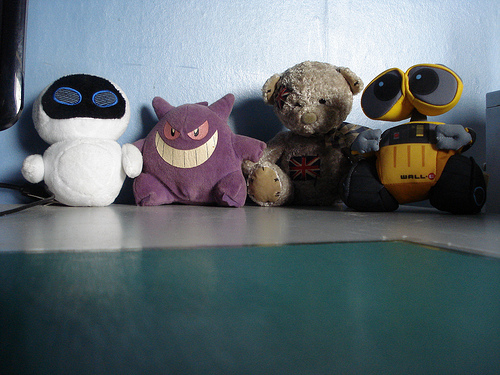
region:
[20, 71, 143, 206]
A white and black stuffed animal.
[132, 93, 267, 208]
A purple stuffed animal.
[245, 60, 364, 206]
A brown teddy bear.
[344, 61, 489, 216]
A yellow and black WALL-E plush toy.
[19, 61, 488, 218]
A row of toys.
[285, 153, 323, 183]
A British flag sewn on the teddy bear.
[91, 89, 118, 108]
The left-most toy has blue eyes.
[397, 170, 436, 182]
The WALL-E logo is sewn on the front of the right-most toy.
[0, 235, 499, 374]
A large green area in front of the toys.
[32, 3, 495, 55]
The backdrop is blue.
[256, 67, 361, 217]
a brown teddy bear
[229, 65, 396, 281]
a brown teddy bear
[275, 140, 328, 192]
a flag of Great Britain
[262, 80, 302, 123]
a flag of Great Britain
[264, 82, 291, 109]
a flag of Great Britain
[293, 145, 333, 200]
a flag of Great Britain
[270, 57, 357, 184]
a brown teddy bear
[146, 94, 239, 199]
a purple monster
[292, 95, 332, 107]
eyes on the teddy bear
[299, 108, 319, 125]
nose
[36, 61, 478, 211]
four stuffed animals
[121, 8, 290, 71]
a blue wall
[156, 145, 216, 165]
the monster is smiling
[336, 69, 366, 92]
ears on the teddy bear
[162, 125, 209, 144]
eyes the monster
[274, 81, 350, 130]
a brown bear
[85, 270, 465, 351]
The color of the table is green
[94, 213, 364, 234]
The color of the table is green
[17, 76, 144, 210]
The stuffed animal is white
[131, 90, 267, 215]
The stuffed animal is purple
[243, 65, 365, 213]
The stuffed animal is beige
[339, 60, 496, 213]
The stuffed animal is black and yellow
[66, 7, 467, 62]
The wall color is baby blue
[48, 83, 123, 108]
The eyes of the stuffed animal are blue and gray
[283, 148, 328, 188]
The UK flag is on the stuffed animal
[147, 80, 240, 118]
The purple monster has horns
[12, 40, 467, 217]
four stuffed toys lines up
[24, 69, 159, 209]
white toy with black face and blue eyes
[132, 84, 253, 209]
purple toy with big white teeth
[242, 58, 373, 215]
light brown teddy bear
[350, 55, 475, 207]
yellow robot stuffed toy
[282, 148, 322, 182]
british flag on teddy bear's body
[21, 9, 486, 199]
blue wall behind stuffed toys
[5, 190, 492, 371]
table stuffed toys are on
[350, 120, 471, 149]
gray hands of robot toy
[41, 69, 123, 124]
black face of white toy